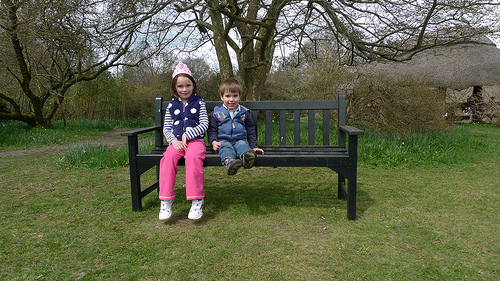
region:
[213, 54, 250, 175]
this is a baby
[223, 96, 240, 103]
the baby is light skinned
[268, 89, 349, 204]
this is a bench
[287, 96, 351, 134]
the bench is wooden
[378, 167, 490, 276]
this is a grass area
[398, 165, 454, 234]
the grass is green in color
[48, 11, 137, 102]
this is a tree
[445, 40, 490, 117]
this is a building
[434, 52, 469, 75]
this is the roof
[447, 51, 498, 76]
the roof is grass thatched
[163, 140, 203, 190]
girl wearing pink pants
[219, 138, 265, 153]
boy wearing blue jeans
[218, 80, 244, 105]
by with blonde hair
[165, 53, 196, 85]
girl with a pink hat on her head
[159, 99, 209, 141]
girl wearing a blue vest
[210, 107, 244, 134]
boy wearing a blue jacket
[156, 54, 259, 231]
two children seating on a bench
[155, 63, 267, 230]
bench with two children on it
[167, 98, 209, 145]
girl with a stripped shirt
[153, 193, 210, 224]
girl wearing white sneakers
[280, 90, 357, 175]
this is a bench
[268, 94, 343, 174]
the bench is wooden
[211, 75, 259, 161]
this is a child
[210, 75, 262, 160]
the child is sitted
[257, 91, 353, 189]
the bench is sitted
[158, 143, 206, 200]
the trousers are pink in color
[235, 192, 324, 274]
the grass are green in color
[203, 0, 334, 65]
this is a tree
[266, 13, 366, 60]
the tree is dry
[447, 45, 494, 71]
this is a hut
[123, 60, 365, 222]
a boy and a girl sitting on a bench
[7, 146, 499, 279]
cut grass beneath bench's seat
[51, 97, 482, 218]
overgrown grass behind bench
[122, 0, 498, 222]
large leafless tree behind bench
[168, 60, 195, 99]
pink tiara-shaped object on girl's head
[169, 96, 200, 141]
girl is wearing a blue vest with large white dots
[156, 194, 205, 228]
girl's feet are not touching the ground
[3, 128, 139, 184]
dirt path through grass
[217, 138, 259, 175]
boy's legs are sticking out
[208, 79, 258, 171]
boy is dressed in blue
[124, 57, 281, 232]
two kids on a bench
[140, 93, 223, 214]
blue shirt and pink pants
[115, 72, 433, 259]
a black wooden bench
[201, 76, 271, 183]
a little boy in all blue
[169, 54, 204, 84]
a tiera on her head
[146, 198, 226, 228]
white and pink shoes on her feet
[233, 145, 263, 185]
bottoms of black shoes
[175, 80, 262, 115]
two smiles on their faces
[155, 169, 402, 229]
a shadow under the bench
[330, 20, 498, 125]
a shelter in the background